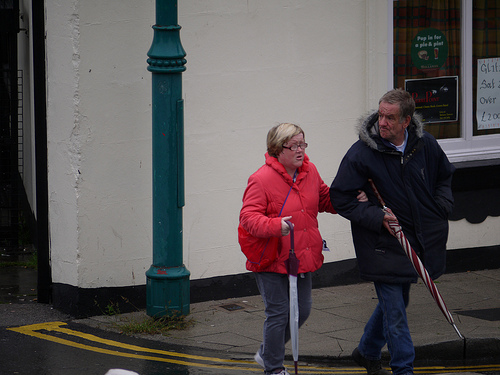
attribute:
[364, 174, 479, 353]
umbrella — striped, red, white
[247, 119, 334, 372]
woman — blond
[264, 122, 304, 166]
hair — short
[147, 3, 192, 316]
post — green, metal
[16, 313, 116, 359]
lines — yellow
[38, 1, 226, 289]
building — chipped, white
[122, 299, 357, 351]
sidewalk — cement, wet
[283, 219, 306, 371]
umbrella — maroon, white, black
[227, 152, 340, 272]
jacket — red, puffy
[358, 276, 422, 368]
jeans — blue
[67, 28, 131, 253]
wall — white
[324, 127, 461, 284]
jacket — dark blue, blue, puffy, black